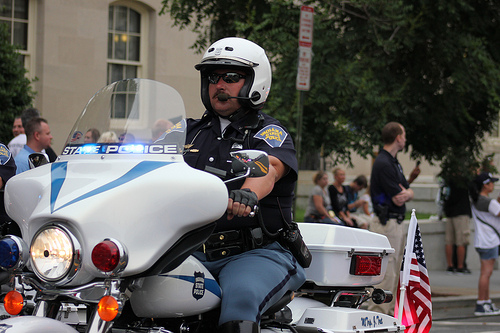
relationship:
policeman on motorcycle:
[141, 38, 311, 332] [4, 76, 407, 331]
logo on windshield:
[59, 145, 180, 155] [59, 78, 188, 154]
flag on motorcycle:
[395, 205, 433, 332] [4, 76, 407, 331]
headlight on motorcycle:
[27, 221, 82, 285] [4, 76, 407, 331]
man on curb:
[370, 120, 414, 329] [365, 264, 500, 318]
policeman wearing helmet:
[141, 38, 311, 332] [194, 36, 271, 107]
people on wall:
[308, 168, 376, 230] [400, 218, 499, 267]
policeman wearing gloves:
[141, 38, 311, 332] [227, 187, 259, 212]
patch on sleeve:
[253, 123, 287, 148] [248, 115, 299, 181]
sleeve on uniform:
[248, 115, 299, 181] [149, 119, 309, 330]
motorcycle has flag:
[4, 76, 407, 331] [395, 205, 433, 332]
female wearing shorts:
[470, 172, 500, 314] [473, 243, 499, 257]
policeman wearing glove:
[141, 38, 311, 332] [225, 188, 258, 213]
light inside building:
[111, 29, 128, 42] [1, 1, 215, 167]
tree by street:
[158, 1, 499, 167] [395, 313, 498, 332]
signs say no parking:
[297, 4, 312, 94] [300, 48, 311, 64]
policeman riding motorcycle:
[141, 38, 311, 332] [4, 76, 407, 331]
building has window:
[1, 1, 215, 167] [104, 2, 143, 121]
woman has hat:
[469, 171, 499, 316] [477, 171, 497, 182]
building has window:
[1, 1, 215, 167] [1, 0, 29, 72]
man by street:
[370, 120, 414, 329] [395, 313, 498, 332]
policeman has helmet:
[141, 38, 311, 332] [194, 36, 271, 107]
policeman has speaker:
[141, 38, 311, 332] [218, 92, 262, 103]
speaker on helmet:
[218, 92, 262, 103] [194, 36, 271, 107]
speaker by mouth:
[218, 92, 262, 103] [210, 92, 232, 103]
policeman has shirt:
[141, 38, 311, 332] [148, 110, 297, 235]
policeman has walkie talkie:
[141, 38, 311, 332] [272, 198, 314, 268]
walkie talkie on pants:
[272, 198, 314, 268] [192, 249, 307, 320]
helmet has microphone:
[194, 36, 271, 107] [218, 92, 262, 103]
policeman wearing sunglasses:
[141, 38, 311, 332] [205, 70, 252, 83]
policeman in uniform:
[141, 38, 311, 332] [149, 119, 309, 330]